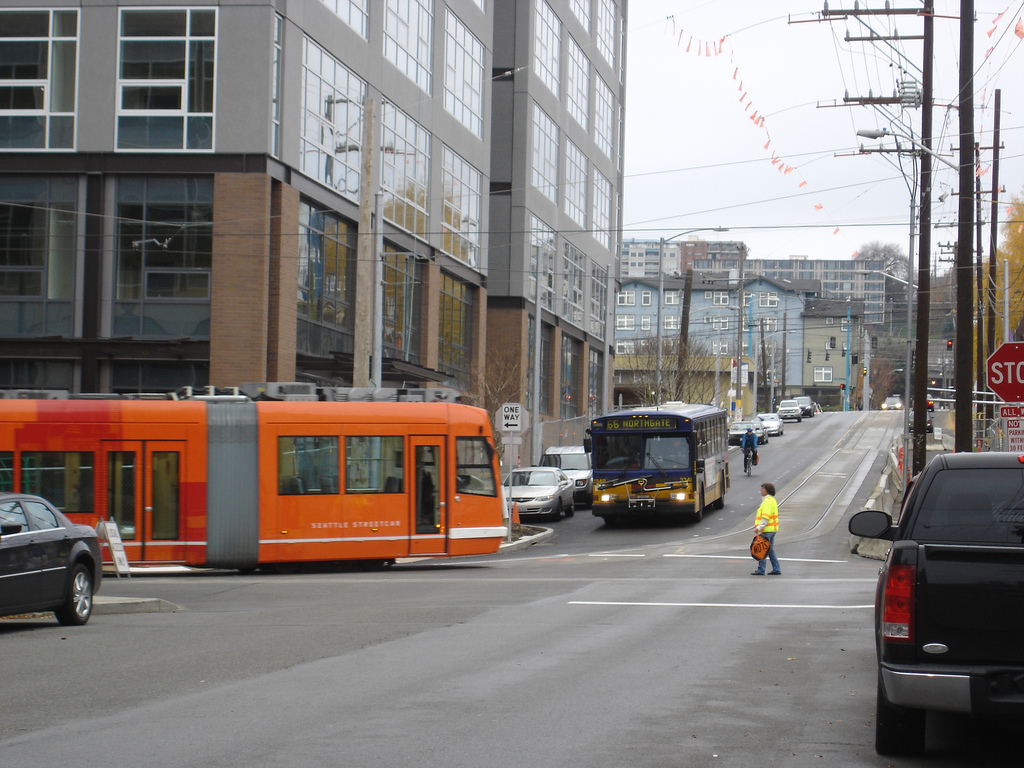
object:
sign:
[503, 404, 522, 431]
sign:
[95, 518, 133, 582]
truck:
[848, 451, 1023, 761]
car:
[0, 493, 102, 625]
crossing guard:
[750, 482, 782, 575]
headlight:
[881, 564, 917, 646]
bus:
[0, 380, 510, 578]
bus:
[581, 401, 729, 527]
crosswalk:
[180, 546, 886, 610]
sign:
[750, 531, 770, 563]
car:
[503, 467, 575, 523]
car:
[531, 445, 594, 510]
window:
[121, 86, 181, 110]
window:
[121, 9, 186, 36]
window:
[191, 9, 218, 36]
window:
[187, 117, 214, 149]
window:
[50, 41, 77, 113]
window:
[52, 9, 77, 36]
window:
[296, 191, 359, 356]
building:
[0, 0, 629, 486]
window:
[277, 436, 340, 496]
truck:
[0, 396, 818, 763]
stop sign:
[986, 341, 1022, 402]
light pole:
[953, 4, 975, 451]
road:
[0, 409, 907, 767]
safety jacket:
[755, 495, 780, 533]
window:
[345, 437, 405, 495]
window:
[455, 436, 498, 497]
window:
[151, 451, 179, 540]